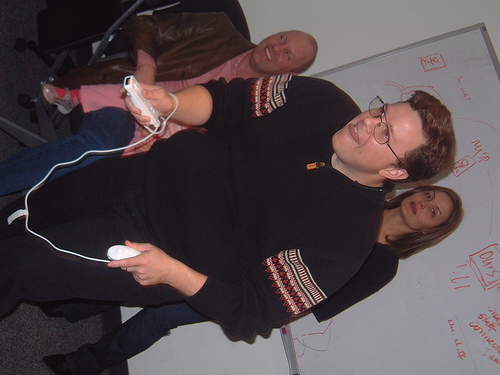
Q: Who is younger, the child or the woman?
A: The child is younger than the woman.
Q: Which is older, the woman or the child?
A: The woman is older than the child.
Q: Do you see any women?
A: Yes, there is a woman.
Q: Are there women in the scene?
A: Yes, there is a woman.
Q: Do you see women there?
A: Yes, there is a woman.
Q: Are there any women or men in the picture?
A: Yes, there is a woman.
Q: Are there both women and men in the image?
A: Yes, there are both a woman and a man.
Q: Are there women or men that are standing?
A: Yes, the woman is standing.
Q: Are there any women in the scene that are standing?
A: Yes, there is a woman that is standing.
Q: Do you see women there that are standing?
A: Yes, there is a woman that is standing.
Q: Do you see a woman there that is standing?
A: Yes, there is a woman that is standing.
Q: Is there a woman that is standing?
A: Yes, there is a woman that is standing.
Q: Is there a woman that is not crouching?
A: Yes, there is a woman that is standing.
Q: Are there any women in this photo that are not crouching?
A: Yes, there is a woman that is standing.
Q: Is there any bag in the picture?
A: No, there are no bags.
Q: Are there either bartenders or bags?
A: No, there are no bags or bartenders.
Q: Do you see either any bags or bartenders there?
A: No, there are no bags or bartenders.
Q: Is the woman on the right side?
A: Yes, the woman is on the right of the image.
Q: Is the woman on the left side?
A: No, the woman is on the right of the image.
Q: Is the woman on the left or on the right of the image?
A: The woman is on the right of the image.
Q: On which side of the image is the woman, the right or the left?
A: The woman is on the right of the image.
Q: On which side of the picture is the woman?
A: The woman is on the right of the image.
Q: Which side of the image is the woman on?
A: The woman is on the right of the image.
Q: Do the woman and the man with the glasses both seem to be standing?
A: Yes, both the woman and the man are standing.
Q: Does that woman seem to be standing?
A: Yes, the woman is standing.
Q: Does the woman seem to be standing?
A: Yes, the woman is standing.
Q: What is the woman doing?
A: The woman is standing.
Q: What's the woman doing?
A: The woman is standing.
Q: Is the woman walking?
A: No, the woman is standing.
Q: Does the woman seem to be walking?
A: No, the woman is standing.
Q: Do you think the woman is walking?
A: No, the woman is standing.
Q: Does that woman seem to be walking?
A: No, the woman is standing.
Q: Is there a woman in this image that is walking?
A: No, there is a woman but she is standing.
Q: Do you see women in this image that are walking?
A: No, there is a woman but she is standing.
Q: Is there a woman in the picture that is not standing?
A: No, there is a woman but she is standing.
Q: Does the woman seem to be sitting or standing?
A: The woman is standing.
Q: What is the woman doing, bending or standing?
A: The woman is standing.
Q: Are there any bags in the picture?
A: No, there are no bags.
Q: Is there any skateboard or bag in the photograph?
A: No, there are no bags or skateboards.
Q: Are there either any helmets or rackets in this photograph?
A: No, there are no helmets or rackets.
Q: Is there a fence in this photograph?
A: No, there are no fences.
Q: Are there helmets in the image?
A: No, there are no helmets.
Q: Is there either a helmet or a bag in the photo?
A: No, there are no helmets or bags.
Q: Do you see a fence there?
A: No, there are no fences.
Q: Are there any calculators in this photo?
A: No, there are no calculators.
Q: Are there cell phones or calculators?
A: No, there are no calculators or cell phones.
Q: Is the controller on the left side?
A: Yes, the controller is on the left of the image.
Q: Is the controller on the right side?
A: No, the controller is on the left of the image.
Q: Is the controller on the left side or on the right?
A: The controller is on the left of the image.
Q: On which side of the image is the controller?
A: The controller is on the left of the image.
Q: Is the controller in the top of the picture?
A: Yes, the controller is in the top of the image.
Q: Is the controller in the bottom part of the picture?
A: No, the controller is in the top of the image.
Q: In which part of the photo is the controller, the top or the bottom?
A: The controller is in the top of the image.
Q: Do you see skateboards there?
A: No, there are no skateboards.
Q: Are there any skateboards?
A: No, there are no skateboards.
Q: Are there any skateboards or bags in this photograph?
A: No, there are no skateboards or bags.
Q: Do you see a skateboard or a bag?
A: No, there are no skateboards or bags.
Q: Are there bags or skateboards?
A: No, there are no skateboards or bags.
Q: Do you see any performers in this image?
A: No, there are no performers.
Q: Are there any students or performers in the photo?
A: No, there are no performers or students.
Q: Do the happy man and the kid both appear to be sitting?
A: Yes, both the man and the kid are sitting.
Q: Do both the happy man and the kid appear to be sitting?
A: Yes, both the man and the kid are sitting.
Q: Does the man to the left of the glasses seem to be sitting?
A: Yes, the man is sitting.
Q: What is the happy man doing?
A: The man is sitting.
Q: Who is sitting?
A: The man is sitting.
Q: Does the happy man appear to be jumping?
A: No, the man is sitting.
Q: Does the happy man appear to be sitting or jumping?
A: The man is sitting.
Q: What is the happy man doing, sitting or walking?
A: The man is sitting.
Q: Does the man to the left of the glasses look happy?
A: Yes, the man is happy.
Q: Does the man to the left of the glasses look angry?
A: No, the man is happy.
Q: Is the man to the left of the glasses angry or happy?
A: The man is happy.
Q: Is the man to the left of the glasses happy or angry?
A: The man is happy.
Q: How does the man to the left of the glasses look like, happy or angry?
A: The man is happy.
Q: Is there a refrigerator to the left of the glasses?
A: No, there is a man to the left of the glasses.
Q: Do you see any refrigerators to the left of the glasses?
A: No, there is a man to the left of the glasses.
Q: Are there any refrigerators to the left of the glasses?
A: No, there is a man to the left of the glasses.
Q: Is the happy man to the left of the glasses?
A: Yes, the man is to the left of the glasses.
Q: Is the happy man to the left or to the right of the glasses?
A: The man is to the left of the glasses.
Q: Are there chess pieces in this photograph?
A: No, there are no chess pieces.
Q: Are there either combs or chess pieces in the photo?
A: No, there are no chess pieces or combs.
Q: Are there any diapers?
A: No, there are no diapers.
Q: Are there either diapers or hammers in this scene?
A: No, there are no diapers or hammers.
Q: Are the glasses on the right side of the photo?
A: Yes, the glasses are on the right of the image.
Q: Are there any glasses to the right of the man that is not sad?
A: Yes, there are glasses to the right of the man.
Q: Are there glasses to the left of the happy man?
A: No, the glasses are to the right of the man.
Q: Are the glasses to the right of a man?
A: Yes, the glasses are to the right of a man.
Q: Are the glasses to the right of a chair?
A: No, the glasses are to the right of a man.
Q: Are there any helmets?
A: No, there are no helmets.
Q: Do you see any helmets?
A: No, there are no helmets.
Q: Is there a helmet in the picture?
A: No, there are no helmets.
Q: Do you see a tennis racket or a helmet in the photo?
A: No, there are no helmets or rackets.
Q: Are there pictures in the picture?
A: No, there are no pictures.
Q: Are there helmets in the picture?
A: No, there are no helmets.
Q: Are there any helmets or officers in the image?
A: No, there are no helmets or officers.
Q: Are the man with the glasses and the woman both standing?
A: Yes, both the man and the woman are standing.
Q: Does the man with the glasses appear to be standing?
A: Yes, the man is standing.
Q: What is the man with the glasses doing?
A: The man is standing.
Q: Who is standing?
A: The man is standing.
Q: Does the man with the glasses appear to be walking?
A: No, the man is standing.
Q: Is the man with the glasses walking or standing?
A: The man is standing.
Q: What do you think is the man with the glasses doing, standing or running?
A: The man is standing.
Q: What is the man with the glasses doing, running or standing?
A: The man is standing.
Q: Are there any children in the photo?
A: Yes, there is a child.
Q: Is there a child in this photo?
A: Yes, there is a child.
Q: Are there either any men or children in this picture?
A: Yes, there is a child.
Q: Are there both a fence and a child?
A: No, there is a child but no fences.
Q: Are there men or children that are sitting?
A: Yes, the child is sitting.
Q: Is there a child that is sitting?
A: Yes, there is a child that is sitting.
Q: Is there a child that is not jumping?
A: Yes, there is a child that is sitting.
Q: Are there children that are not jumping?
A: Yes, there is a child that is sitting.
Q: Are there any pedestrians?
A: No, there are no pedestrians.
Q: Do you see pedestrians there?
A: No, there are no pedestrians.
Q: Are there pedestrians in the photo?
A: No, there are no pedestrians.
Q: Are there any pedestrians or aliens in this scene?
A: No, there are no pedestrians or aliens.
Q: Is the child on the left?
A: Yes, the child is on the left of the image.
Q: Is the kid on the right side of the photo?
A: No, the kid is on the left of the image.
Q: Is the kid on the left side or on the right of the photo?
A: The kid is on the left of the image.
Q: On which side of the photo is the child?
A: The child is on the left of the image.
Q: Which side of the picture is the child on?
A: The child is on the left of the image.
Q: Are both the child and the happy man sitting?
A: Yes, both the child and the man are sitting.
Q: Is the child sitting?
A: Yes, the child is sitting.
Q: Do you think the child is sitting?
A: Yes, the child is sitting.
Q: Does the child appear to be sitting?
A: Yes, the child is sitting.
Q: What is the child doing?
A: The child is sitting.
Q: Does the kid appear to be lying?
A: No, the kid is sitting.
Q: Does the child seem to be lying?
A: No, the child is sitting.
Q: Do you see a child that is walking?
A: No, there is a child but he is sitting.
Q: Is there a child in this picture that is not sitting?
A: No, there is a child but he is sitting.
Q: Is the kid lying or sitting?
A: The kid is sitting.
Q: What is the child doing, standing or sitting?
A: The child is sitting.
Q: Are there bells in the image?
A: No, there are no bells.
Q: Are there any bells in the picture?
A: No, there are no bells.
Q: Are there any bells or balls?
A: No, there are no bells or balls.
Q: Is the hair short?
A: Yes, the hair is short.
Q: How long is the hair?
A: The hair is short.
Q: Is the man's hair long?
A: No, the hair is short.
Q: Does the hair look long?
A: No, the hair is short.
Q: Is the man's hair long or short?
A: The hair is short.